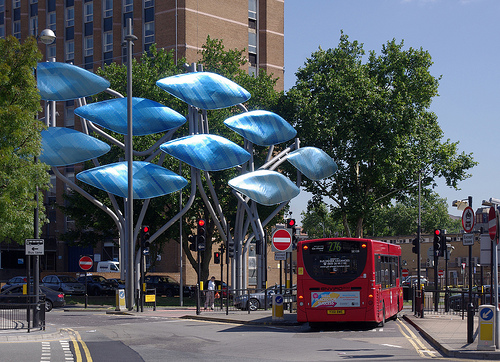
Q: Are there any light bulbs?
A: No, there are no light bulbs.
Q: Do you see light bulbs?
A: No, there are no light bulbs.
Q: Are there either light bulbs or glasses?
A: No, there are no light bulbs or glasses.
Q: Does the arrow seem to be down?
A: Yes, the arrow is down.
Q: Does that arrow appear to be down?
A: Yes, the arrow is down.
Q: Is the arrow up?
A: No, the arrow is down.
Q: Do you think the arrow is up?
A: No, the arrow is down.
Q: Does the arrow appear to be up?
A: No, the arrow is down.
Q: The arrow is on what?
A: The arrow is on the sign.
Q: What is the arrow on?
A: The arrow is on the sign.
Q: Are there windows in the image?
A: Yes, there are windows.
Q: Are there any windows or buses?
A: Yes, there are windows.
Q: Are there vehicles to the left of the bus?
A: Yes, there are vehicles to the left of the bus.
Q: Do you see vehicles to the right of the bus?
A: No, the vehicles are to the left of the bus.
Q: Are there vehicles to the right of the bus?
A: No, the vehicles are to the left of the bus.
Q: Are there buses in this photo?
A: Yes, there is a bus.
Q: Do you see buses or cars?
A: Yes, there is a bus.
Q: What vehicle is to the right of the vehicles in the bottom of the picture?
A: The vehicle is a bus.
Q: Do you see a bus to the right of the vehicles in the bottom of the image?
A: Yes, there is a bus to the right of the vehicles.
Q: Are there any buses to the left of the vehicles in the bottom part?
A: No, the bus is to the right of the vehicles.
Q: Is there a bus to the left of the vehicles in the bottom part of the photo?
A: No, the bus is to the right of the vehicles.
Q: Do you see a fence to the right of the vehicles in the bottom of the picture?
A: No, there is a bus to the right of the vehicles.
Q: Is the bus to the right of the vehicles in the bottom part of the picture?
A: Yes, the bus is to the right of the vehicles.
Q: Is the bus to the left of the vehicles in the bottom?
A: No, the bus is to the right of the vehicles.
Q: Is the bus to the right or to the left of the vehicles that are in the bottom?
A: The bus is to the right of the vehicles.